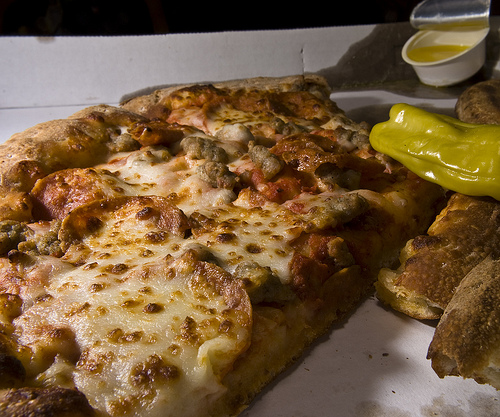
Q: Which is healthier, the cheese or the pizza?
A: The cheese is healthier than the pizza.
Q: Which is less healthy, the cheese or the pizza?
A: The pizza is less healthy than the cheese.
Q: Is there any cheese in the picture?
A: Yes, there is cheese.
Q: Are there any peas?
A: No, there are no peas.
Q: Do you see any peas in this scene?
A: No, there are no peas.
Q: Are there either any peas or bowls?
A: No, there are no peas or bowls.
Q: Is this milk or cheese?
A: This is cheese.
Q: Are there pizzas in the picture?
A: Yes, there is a pizza.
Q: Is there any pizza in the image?
A: Yes, there is a pizza.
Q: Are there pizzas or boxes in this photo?
A: Yes, there is a pizza.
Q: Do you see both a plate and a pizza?
A: No, there is a pizza but no plates.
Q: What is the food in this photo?
A: The food is a pizza.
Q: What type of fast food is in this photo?
A: The fast food is a pizza.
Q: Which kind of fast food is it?
A: The food is a pizza.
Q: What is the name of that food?
A: This is a pizza.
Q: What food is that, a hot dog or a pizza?
A: This is a pizza.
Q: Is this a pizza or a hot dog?
A: This is a pizza.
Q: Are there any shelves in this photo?
A: No, there are no shelves.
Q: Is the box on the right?
A: Yes, the box is on the right of the image.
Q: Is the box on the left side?
A: No, the box is on the right of the image.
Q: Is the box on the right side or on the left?
A: The box is on the right of the image.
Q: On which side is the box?
A: The box is on the right of the image.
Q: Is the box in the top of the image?
A: Yes, the box is in the top of the image.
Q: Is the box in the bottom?
A: No, the box is in the top of the image.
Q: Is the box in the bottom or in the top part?
A: The box is in the top of the image.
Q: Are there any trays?
A: No, there are no trays.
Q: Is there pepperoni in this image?
A: Yes, there is pepperoni.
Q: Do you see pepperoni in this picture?
A: Yes, there is pepperoni.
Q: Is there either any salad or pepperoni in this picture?
A: Yes, there is pepperoni.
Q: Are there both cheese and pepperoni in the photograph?
A: Yes, there are both pepperoni and cheese.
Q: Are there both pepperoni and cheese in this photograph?
A: Yes, there are both pepperoni and cheese.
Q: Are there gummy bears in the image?
A: No, there are no gummy bears.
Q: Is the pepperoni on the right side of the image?
A: No, the pepperoni is on the left of the image.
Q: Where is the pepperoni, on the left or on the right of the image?
A: The pepperoni is on the left of the image.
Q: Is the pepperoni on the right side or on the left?
A: The pepperoni is on the left of the image.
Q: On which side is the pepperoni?
A: The pepperoni is on the left of the image.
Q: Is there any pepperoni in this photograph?
A: Yes, there is pepperoni.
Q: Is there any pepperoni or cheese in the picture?
A: Yes, there is pepperoni.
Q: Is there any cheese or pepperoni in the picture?
A: Yes, there is pepperoni.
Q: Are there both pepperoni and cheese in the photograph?
A: Yes, there are both pepperoni and cheese.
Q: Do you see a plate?
A: No, there are no plates.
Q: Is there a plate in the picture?
A: No, there are no plates.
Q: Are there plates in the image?
A: No, there are no plates.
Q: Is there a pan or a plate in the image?
A: No, there are no plates or pans.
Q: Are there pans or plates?
A: No, there are no plates or pans.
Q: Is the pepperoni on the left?
A: Yes, the pepperoni is on the left of the image.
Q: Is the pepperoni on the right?
A: No, the pepperoni is on the left of the image.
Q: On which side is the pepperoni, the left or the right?
A: The pepperoni is on the left of the image.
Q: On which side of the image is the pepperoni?
A: The pepperoni is on the left of the image.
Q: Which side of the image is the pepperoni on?
A: The pepperoni is on the left of the image.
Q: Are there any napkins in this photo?
A: No, there are no napkins.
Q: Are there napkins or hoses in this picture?
A: No, there are no napkins or hoses.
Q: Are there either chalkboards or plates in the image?
A: No, there are no plates or chalkboards.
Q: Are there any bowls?
A: No, there are no bowls.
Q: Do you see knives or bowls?
A: No, there are no bowls or knives.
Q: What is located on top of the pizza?
A: The sausage is on top of the pizza.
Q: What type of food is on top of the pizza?
A: The food is a sausage.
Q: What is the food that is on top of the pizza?
A: The food is a sausage.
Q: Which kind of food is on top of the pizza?
A: The food is a sausage.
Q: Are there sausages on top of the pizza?
A: Yes, there is a sausage on top of the pizza.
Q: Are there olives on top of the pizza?
A: No, there is a sausage on top of the pizza.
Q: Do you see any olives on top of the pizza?
A: No, there is a sausage on top of the pizza.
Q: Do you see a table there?
A: Yes, there is a table.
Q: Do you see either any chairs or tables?
A: Yes, there is a table.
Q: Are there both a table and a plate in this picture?
A: No, there is a table but no plates.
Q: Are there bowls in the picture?
A: No, there are no bowls.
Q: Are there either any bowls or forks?
A: No, there are no bowls or forks.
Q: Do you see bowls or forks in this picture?
A: No, there are no bowls or forks.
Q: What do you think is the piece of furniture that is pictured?
A: The piece of furniture is a table.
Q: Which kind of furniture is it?
A: The piece of furniture is a table.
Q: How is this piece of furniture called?
A: This is a table.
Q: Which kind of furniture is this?
A: This is a table.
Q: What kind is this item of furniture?
A: This is a table.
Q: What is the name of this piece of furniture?
A: This is a table.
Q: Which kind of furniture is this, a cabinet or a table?
A: This is a table.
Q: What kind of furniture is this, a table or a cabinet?
A: This is a table.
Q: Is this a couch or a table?
A: This is a table.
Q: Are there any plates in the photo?
A: No, there are no plates.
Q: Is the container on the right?
A: Yes, the container is on the right of the image.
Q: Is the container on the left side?
A: No, the container is on the right of the image.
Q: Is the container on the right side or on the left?
A: The container is on the right of the image.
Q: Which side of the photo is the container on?
A: The container is on the right of the image.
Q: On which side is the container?
A: The container is on the right of the image.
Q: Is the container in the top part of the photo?
A: Yes, the container is in the top of the image.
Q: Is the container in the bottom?
A: No, the container is in the top of the image.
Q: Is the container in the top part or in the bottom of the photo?
A: The container is in the top of the image.